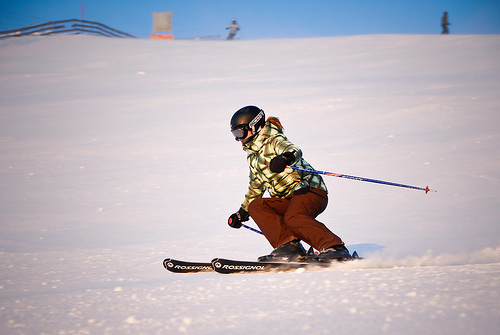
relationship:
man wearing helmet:
[227, 105, 347, 262] [230, 99, 266, 138]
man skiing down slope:
[227, 103, 347, 262] [0, 33, 497, 333]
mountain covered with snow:
[2, 33, 497, 331] [4, 34, 495, 329]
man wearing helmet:
[227, 105, 347, 262] [226, 102, 266, 140]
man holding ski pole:
[227, 105, 347, 262] [288, 162, 438, 193]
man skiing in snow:
[227, 105, 347, 262] [4, 34, 495, 329]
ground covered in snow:
[5, 32, 497, 331] [4, 34, 495, 329]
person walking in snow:
[436, 9, 451, 34] [4, 34, 495, 329]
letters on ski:
[223, 259, 268, 271] [209, 257, 320, 276]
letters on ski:
[172, 262, 211, 270] [161, 256, 221, 274]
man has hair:
[227, 105, 347, 262] [265, 113, 285, 135]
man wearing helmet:
[227, 105, 347, 262] [230, 103, 268, 144]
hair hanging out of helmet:
[265, 113, 285, 135] [230, 103, 268, 144]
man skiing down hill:
[227, 105, 347, 262] [2, 34, 498, 333]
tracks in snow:
[343, 247, 499, 274] [4, 34, 495, 329]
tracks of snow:
[343, 249, 499, 270] [180, 241, 493, 299]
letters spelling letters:
[172, 263, 211, 270] [172, 263, 211, 270]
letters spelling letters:
[223, 265, 266, 271] [223, 265, 266, 271]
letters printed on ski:
[172, 263, 211, 270] [160, 256, 214, 273]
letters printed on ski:
[223, 265, 266, 271] [208, 255, 333, 275]